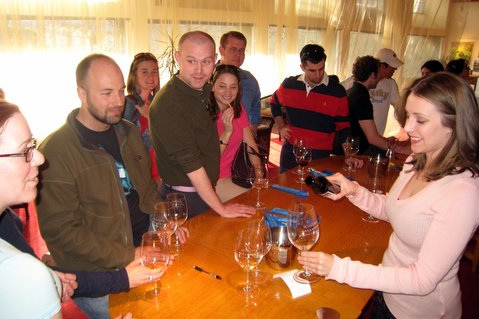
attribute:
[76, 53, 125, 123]
head — man's, balding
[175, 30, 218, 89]
head — man's, balding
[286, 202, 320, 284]
glass — partially full, large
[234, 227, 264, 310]
glass — large, partially full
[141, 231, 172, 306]
glass — partially full, large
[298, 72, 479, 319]
lady — here, smiling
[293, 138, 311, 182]
glass — empty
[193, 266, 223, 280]
pen — here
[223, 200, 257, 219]
hand — in front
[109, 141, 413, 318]
table — shiny, wooden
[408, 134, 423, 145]
mouth — open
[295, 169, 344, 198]
bottle — here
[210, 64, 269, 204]
girl — smiling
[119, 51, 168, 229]
girl — smiling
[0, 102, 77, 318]
person — watching